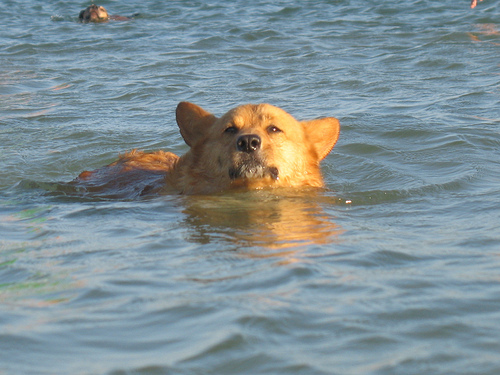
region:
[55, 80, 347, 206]
dog swimming in water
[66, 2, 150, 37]
brown and tan dog swimming in water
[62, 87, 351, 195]
tan dog swimming water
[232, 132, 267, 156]
black nose on dog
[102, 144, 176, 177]
wet fur of tan dog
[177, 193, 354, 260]
reflection of dog in water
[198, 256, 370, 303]
dark ripples in water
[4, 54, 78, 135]
light reflecting on water surface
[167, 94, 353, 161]
tan dog ears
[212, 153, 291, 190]
brown dark dog mouth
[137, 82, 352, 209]
brown dog swimming in water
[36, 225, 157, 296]
ripples in greenish blue water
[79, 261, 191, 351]
ripples in greenish blue water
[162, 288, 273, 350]
ripples in greenish blue water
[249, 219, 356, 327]
ripples in greenish blue water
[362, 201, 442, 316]
ripples in greenish blue water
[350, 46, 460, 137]
ripples in greenish blue water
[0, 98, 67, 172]
ripples in greenish blue water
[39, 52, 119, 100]
ripples in greenish blue water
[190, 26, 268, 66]
ripples in greenish blue water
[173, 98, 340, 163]
Brown ears of a dog in the water.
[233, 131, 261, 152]
Black nose on the face of a dog.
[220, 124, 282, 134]
Eyes on a dog in the water.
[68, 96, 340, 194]
A light brown dog swimming in water.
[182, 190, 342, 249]
Reflection of a tan dog in the water.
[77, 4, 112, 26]
A dog back in the background of the water.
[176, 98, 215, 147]
A dog's right ear that's close to the camera.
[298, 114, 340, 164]
A dog's left ear that is closest to the camera.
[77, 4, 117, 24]
Head of a distant brown dog.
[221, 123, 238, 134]
A dog's right side eye closest to the camera.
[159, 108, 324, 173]
this is a dog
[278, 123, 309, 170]
the dog is brown in color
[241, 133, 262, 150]
this is the nose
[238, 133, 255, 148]
the nose is black in color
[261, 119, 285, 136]
this is the eye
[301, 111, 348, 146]
this is the ear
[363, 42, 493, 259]
this is a water body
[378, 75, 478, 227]
the water is calm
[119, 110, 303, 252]
the dog is in water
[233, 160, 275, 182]
this is the mouth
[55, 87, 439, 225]
this dog is swimming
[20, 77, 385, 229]
a dog swimming in water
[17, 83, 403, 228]
a wet dog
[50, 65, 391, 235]
the dog's fur is wet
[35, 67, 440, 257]
the dog is treading water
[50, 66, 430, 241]
the dog is keeping its head above water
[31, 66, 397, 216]
the dog has wet fur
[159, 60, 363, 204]
the head of the dog above the surface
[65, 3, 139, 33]
another dog in the water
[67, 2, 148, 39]
this dog is also treading water